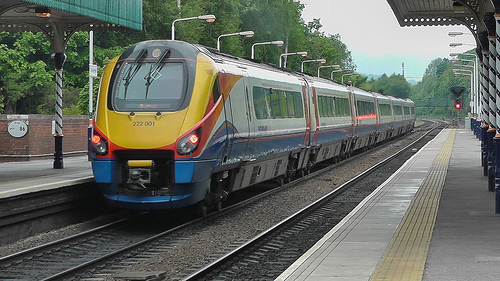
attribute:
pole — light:
[239, 29, 281, 59]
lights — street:
[175, 21, 362, 90]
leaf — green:
[34, 65, 45, 77]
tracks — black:
[0, 121, 447, 280]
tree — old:
[200, 0, 249, 55]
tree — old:
[144, 0, 212, 39]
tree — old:
[245, 0, 305, 62]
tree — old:
[292, 10, 323, 67]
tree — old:
[316, 30, 356, 77]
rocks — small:
[195, 202, 267, 260]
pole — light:
[316, 62, 340, 77]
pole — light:
[300, 57, 326, 72]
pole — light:
[330, 67, 350, 81]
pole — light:
[455, 42, 495, 136]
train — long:
[78, 34, 416, 223]